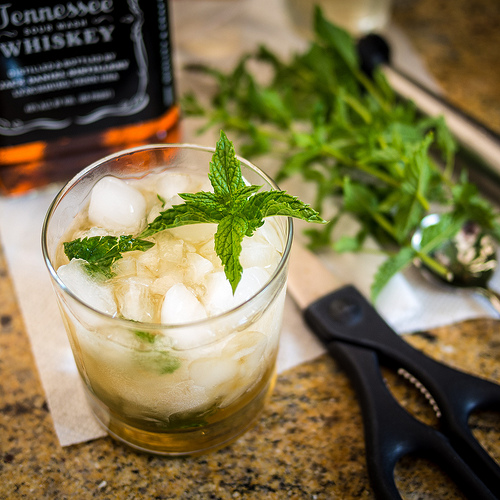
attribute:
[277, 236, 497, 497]
scissors — silver, metal, black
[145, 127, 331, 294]
leaf — healthy, green, small, dark, mint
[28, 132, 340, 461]
glass — clear, ready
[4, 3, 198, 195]
bottle — large, wide, dark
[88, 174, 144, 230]
ice cube — cold, clear, cloudy, freezing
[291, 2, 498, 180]
spoon — silver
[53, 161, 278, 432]
drink — mixed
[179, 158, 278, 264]
leaf — green